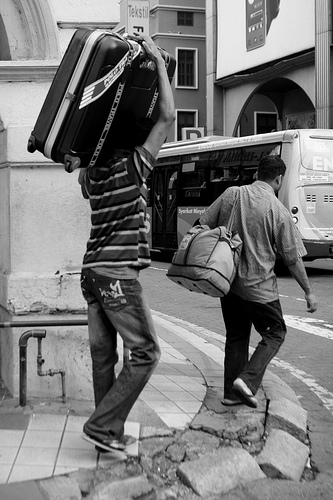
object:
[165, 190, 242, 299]
bag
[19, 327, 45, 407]
pipes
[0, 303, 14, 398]
concrete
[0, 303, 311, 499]
sidewalk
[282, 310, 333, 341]
line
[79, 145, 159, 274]
shirt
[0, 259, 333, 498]
ground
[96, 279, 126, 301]
design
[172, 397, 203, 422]
brick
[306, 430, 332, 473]
brick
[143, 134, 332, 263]
bus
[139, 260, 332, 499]
street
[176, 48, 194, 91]
window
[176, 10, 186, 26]
window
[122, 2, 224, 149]
building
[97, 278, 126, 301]
writing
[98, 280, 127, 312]
back pocket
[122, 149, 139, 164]
shoulder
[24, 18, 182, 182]
suitcase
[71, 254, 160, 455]
pants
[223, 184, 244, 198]
shoulder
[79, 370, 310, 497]
curb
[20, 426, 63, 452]
square tiles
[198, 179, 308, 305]
shirt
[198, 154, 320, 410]
man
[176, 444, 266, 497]
rocks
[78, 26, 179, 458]
man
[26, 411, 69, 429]
square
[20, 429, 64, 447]
square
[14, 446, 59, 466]
square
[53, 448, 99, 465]
square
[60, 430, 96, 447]
square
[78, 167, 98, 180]
shoulder